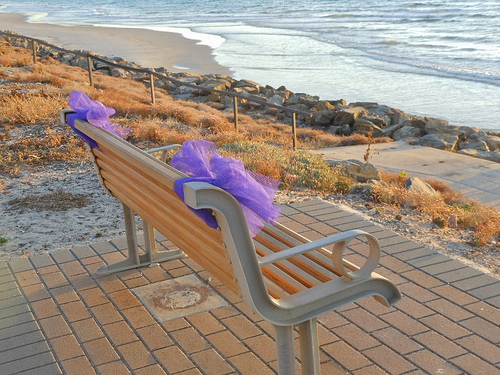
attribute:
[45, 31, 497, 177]
rocks — large 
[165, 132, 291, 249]
bow — purple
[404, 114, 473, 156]
rock — gray, large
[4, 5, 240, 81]
beach — small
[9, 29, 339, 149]
rail — long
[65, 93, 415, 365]
bench — outdoor, beige, wood, metal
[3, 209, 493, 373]
patio — bricked, tiled, outdoor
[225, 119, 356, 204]
grass — brown, green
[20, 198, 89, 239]
sand — gray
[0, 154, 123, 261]
area — small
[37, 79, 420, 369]
bench — metal, wood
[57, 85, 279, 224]
bows — purple